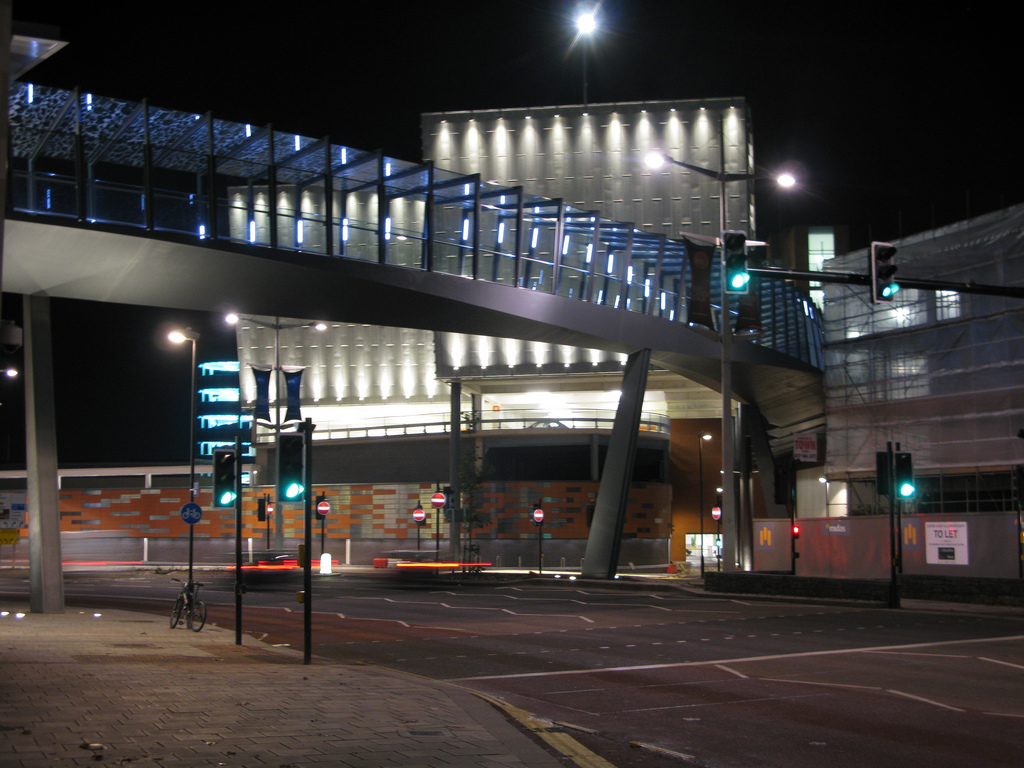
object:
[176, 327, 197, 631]
pole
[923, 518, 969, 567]
poster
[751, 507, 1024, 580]
fence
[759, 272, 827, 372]
glass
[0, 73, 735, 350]
glass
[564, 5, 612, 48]
light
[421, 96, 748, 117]
roof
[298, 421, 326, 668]
pole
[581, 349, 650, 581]
column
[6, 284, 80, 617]
column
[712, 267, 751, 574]
column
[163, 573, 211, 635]
bicycle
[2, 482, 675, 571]
wall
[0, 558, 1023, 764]
lane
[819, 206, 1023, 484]
buildings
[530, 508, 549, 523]
signs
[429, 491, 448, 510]
signs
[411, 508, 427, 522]
signs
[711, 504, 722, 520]
signs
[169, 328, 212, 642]
streetlamp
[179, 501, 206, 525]
sign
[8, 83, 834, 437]
walkway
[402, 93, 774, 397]
building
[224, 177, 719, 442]
building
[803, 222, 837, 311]
building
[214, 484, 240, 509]
light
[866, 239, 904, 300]
light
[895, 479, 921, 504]
light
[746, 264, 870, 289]
pole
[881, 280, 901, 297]
light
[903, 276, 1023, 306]
pole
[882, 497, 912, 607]
pole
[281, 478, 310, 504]
light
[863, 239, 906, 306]
light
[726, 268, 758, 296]
light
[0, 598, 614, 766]
sidewalk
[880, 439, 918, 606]
signal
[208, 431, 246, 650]
signal